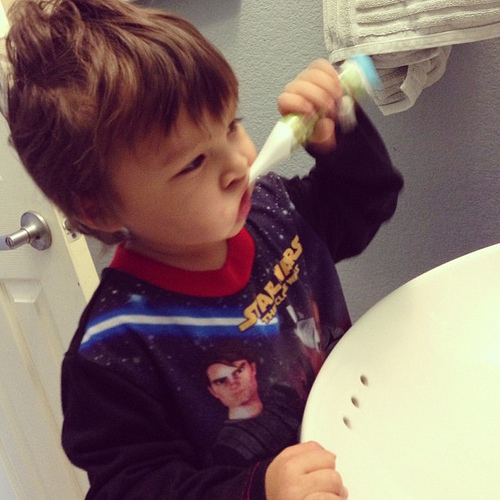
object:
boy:
[0, 0, 402, 500]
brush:
[241, 52, 382, 195]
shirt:
[58, 100, 402, 500]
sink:
[299, 237, 500, 500]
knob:
[1, 210, 52, 255]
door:
[0, 132, 99, 500]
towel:
[321, 0, 500, 63]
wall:
[408, 105, 499, 219]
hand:
[276, 57, 349, 151]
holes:
[360, 375, 369, 388]